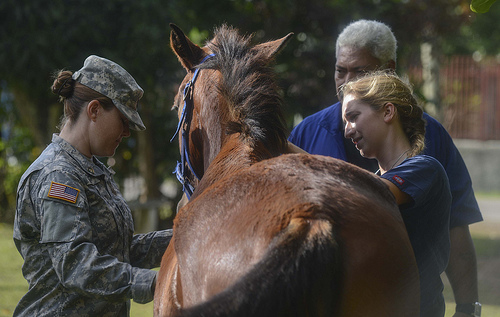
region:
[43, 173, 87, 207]
american flag patch on womans arm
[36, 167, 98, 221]
american flag patch on womans arm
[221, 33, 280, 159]
brown and black mane of horse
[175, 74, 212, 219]
blue reins on horse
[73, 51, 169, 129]
camo army hat on woman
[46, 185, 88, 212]
patch of American flag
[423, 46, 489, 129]
blurry red metal fence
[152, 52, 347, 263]
brown horse touched by people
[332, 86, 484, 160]
woman with blonde hair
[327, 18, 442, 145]
man with white hair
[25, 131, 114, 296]
camo army uniform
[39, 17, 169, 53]
green large trees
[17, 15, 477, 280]
a few people around a horse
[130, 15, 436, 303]
a young bay horse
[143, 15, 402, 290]
a horse with winter coat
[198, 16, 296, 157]
a short black mane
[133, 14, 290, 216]
a horse with a blue halter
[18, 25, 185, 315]
a woman in military uniform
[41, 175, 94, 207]
an american flag patch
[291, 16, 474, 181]
a man with short, white hair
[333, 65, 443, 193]
a woman with a braid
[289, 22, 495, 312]
two people wearing blue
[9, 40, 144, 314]
A woman wearing a military uniform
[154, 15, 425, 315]
Brown horse wearing a blue bridle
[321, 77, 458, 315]
Young women helping a horse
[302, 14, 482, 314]
Older man watching a horse be cared for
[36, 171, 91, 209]
USA flag patched on a uniform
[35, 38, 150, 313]
A woman caring for a horse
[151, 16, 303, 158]
Black and brown horse hair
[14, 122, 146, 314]
USA military jacket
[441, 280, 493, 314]
Man's watch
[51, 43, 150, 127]
USA military hat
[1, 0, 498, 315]
An outdoor photo of people surrounding a horse.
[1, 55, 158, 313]
A standing veteran woman.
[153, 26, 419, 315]
A reddish brown haired horse.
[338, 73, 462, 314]
A blonde woman tending to the horse.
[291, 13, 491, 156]
An older man standing beside the horse.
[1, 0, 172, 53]
The trees with green foliage.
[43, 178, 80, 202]
The U.S.A. flag badge.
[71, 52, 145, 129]
The grey and tan camouflage cap.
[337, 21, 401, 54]
The man's white hair.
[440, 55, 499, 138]
The red colored wooden fence.